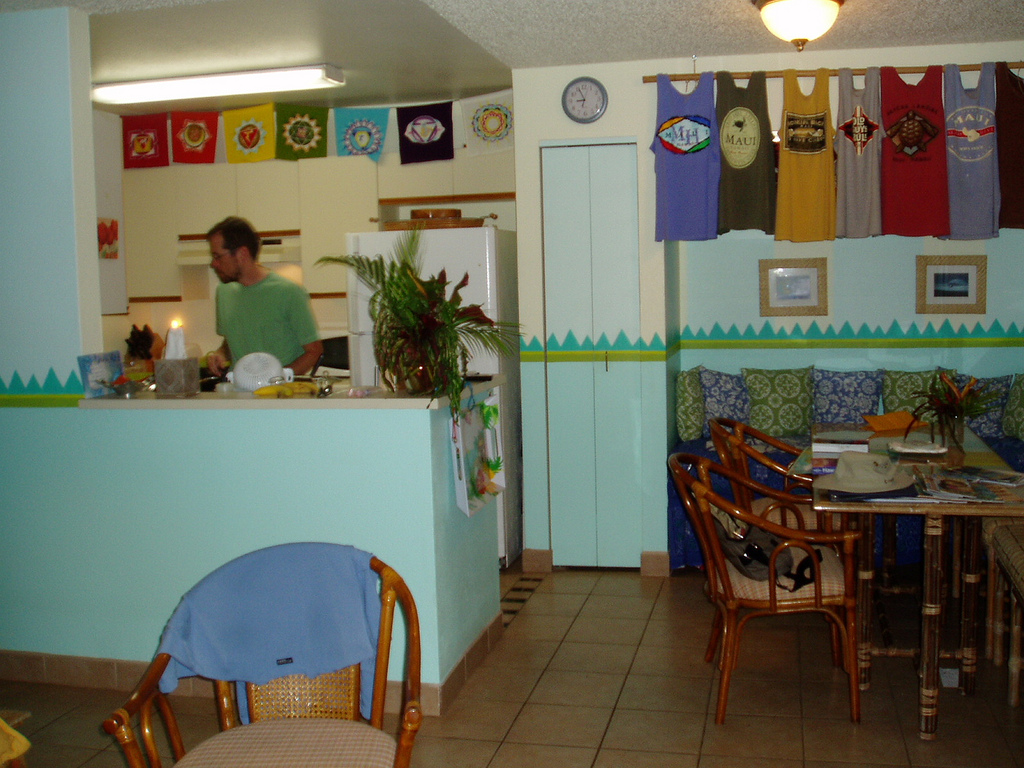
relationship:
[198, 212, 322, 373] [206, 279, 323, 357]
man wearing a green shirt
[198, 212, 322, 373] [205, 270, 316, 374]
man wearing shirt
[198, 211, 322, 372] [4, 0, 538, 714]
man standing in kitchen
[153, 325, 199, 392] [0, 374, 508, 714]
tissue on counter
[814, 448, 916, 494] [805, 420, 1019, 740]
hat on table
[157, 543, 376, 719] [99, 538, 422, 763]
cloth on chair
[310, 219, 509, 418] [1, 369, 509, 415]
plant on counter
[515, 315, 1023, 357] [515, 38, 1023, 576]
trim on wall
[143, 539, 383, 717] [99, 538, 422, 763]
shirt draped over chair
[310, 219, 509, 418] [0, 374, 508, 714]
plant on counter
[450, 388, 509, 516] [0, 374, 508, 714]
picture on side of counter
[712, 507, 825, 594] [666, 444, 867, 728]
bag on chair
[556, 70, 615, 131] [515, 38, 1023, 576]
clock on wall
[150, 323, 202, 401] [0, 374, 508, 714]
tissue box on counter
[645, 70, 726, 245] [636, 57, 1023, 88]
shirt hanging on bar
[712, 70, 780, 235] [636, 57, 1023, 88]
shirt hanging on bar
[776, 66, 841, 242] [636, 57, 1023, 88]
shirt hanging on bar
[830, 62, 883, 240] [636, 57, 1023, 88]
shirt hanging on bar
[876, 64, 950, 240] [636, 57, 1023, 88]
shirt hanging on bar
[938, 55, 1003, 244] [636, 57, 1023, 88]
shirt hanging on bar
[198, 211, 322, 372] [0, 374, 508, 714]
man behind counter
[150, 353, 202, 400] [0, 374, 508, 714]
tissue box on counter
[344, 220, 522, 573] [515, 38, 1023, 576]
refrigerator next to wall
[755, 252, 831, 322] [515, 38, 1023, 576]
picture on wall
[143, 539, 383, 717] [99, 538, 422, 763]
shirt on chair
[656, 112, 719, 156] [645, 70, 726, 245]
maui on shirt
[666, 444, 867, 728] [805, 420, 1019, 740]
chair next to table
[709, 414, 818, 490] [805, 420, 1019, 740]
chair next to table